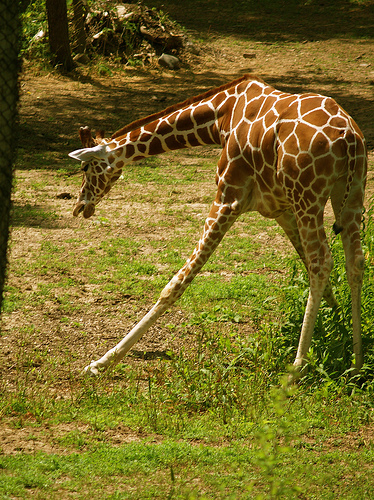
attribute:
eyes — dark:
[78, 161, 91, 175]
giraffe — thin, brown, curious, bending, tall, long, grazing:
[65, 68, 372, 384]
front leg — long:
[92, 200, 230, 368]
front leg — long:
[269, 207, 341, 316]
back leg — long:
[291, 205, 333, 375]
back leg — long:
[339, 183, 373, 373]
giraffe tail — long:
[333, 143, 362, 239]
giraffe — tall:
[37, 40, 373, 401]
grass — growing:
[1, 0, 372, 495]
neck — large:
[119, 89, 223, 163]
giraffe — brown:
[12, 79, 365, 388]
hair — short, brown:
[103, 68, 269, 137]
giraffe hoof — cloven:
[78, 360, 109, 377]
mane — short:
[110, 71, 269, 139]